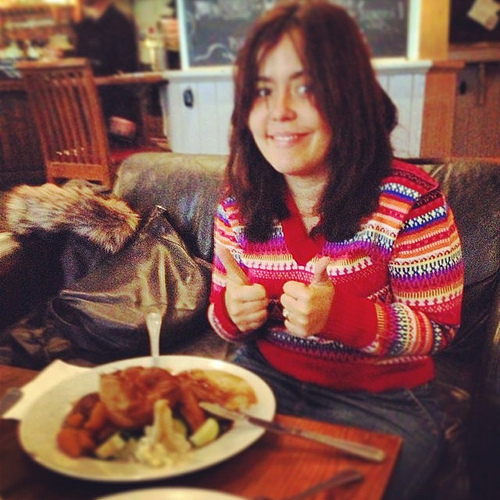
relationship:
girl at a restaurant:
[208, 4, 465, 497] [1, 1, 497, 498]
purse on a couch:
[48, 205, 210, 355] [4, 149, 496, 426]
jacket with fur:
[5, 181, 140, 274] [8, 184, 104, 221]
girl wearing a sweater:
[208, 4, 465, 497] [209, 161, 463, 371]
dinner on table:
[19, 353, 279, 481] [3, 361, 403, 498]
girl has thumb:
[208, 4, 465, 497] [211, 243, 247, 279]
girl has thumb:
[208, 4, 465, 497] [312, 256, 332, 282]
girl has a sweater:
[208, 4, 465, 497] [209, 161, 463, 371]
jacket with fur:
[5, 181, 143, 374] [6, 183, 130, 242]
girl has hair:
[208, 4, 465, 497] [229, 1, 376, 96]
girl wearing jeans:
[208, 4, 465, 497] [228, 342, 448, 471]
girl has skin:
[208, 4, 465, 497] [301, 110, 320, 127]